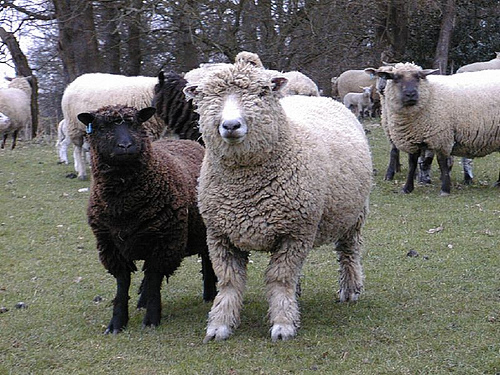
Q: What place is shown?
A: It is a field.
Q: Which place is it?
A: It is a field.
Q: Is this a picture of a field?
A: Yes, it is showing a field.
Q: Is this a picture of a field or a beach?
A: It is showing a field.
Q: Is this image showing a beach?
A: No, the picture is showing a field.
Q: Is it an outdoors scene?
A: Yes, it is outdoors.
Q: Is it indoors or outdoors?
A: It is outdoors.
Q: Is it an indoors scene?
A: No, it is outdoors.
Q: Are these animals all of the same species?
A: Yes, all the animals are sheep.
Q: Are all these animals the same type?
A: Yes, all the animals are sheep.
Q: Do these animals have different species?
A: No, all the animals are sheep.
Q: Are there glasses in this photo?
A: No, there are no glasses.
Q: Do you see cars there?
A: No, there are no cars.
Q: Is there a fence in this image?
A: Yes, there is a fence.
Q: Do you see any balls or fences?
A: Yes, there is a fence.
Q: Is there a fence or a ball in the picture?
A: Yes, there is a fence.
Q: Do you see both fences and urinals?
A: No, there is a fence but no urinals.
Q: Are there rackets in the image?
A: No, there are no rackets.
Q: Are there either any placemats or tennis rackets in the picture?
A: No, there are no tennis rackets or placemats.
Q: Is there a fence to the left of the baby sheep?
A: Yes, there is a fence to the left of the sheep.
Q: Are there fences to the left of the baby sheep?
A: Yes, there is a fence to the left of the sheep.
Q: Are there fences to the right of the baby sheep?
A: No, the fence is to the left of the sheep.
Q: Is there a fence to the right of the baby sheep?
A: No, the fence is to the left of the sheep.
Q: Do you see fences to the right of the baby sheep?
A: No, the fence is to the left of the sheep.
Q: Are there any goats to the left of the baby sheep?
A: No, there is a fence to the left of the sheep.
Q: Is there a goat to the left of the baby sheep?
A: No, there is a fence to the left of the sheep.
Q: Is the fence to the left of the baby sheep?
A: Yes, the fence is to the left of the sheep.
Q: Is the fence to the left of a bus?
A: No, the fence is to the left of the sheep.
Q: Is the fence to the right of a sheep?
A: Yes, the fence is to the right of a sheep.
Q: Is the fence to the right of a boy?
A: No, the fence is to the right of a sheep.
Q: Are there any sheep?
A: Yes, there is a sheep.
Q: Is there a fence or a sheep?
A: Yes, there is a sheep.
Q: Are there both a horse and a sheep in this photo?
A: No, there is a sheep but no horses.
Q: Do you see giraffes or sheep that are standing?
A: Yes, the sheep is standing.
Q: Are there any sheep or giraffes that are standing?
A: Yes, the sheep is standing.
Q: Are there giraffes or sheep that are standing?
A: Yes, the sheep is standing.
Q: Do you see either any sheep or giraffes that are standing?
A: Yes, the sheep is standing.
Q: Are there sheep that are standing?
A: Yes, there is a sheep that is standing.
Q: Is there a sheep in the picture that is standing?
A: Yes, there is a sheep that is standing.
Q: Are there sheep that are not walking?
A: Yes, there is a sheep that is standing.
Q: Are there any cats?
A: No, there are no cats.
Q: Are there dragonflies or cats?
A: No, there are no cats or dragonflies.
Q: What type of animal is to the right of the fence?
A: The animal is a sheep.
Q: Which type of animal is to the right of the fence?
A: The animal is a sheep.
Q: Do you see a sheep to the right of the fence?
A: Yes, there is a sheep to the right of the fence.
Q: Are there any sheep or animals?
A: Yes, there is a sheep.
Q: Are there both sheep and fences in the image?
A: Yes, there are both a sheep and a fence.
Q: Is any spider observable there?
A: No, there are no spiders.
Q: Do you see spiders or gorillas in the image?
A: No, there are no spiders or gorillas.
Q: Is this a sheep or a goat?
A: This is a sheep.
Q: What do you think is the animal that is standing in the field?
A: The animal is a sheep.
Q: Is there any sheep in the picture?
A: Yes, there is a sheep.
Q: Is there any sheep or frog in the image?
A: Yes, there is a sheep.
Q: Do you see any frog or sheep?
A: Yes, there is a sheep.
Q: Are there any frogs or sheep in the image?
A: Yes, there is a sheep.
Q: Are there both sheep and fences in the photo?
A: Yes, there are both a sheep and a fence.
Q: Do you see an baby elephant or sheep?
A: Yes, there is a baby sheep.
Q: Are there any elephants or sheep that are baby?
A: Yes, the sheep is a baby.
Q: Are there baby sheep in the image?
A: Yes, there is a baby sheep.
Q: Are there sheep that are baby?
A: Yes, there is a sheep that is a baby.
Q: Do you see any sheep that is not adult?
A: Yes, there is an baby sheep.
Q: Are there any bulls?
A: No, there are no bulls.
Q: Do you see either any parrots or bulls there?
A: No, there are no bulls or parrots.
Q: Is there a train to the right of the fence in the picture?
A: No, there is a sheep to the right of the fence.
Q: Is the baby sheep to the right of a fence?
A: Yes, the sheep is to the right of a fence.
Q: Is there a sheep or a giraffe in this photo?
A: Yes, there is a sheep.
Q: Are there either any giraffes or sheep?
A: Yes, there is a sheep.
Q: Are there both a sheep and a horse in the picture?
A: No, there is a sheep but no horses.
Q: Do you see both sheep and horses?
A: No, there is a sheep but no horses.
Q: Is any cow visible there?
A: No, there are no cows.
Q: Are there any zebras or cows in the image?
A: No, there are no cows or zebras.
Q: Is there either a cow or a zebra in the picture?
A: No, there are no cows or zebras.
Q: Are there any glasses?
A: No, there are no glasses.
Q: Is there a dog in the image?
A: No, there are no dogs.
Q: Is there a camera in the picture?
A: Yes, there is a camera.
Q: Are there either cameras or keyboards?
A: Yes, there is a camera.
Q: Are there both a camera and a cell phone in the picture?
A: No, there is a camera but no cell phones.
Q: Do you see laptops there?
A: No, there are no laptops.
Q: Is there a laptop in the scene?
A: No, there are no laptops.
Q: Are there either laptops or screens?
A: No, there are no laptops or screens.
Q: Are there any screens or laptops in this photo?
A: No, there are no laptops or screens.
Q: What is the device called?
A: The device is a camera.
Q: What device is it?
A: The device is a camera.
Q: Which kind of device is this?
A: This is a camera.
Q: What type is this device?
A: This is a camera.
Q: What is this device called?
A: This is a camera.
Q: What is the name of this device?
A: This is a camera.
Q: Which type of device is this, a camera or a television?
A: This is a camera.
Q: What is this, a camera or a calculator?
A: This is a camera.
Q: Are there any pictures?
A: No, there are no pictures.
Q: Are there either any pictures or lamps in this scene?
A: No, there are no pictures or lamps.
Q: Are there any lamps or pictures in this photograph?
A: No, there are no pictures or lamps.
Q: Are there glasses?
A: No, there are no glasses.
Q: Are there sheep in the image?
A: Yes, there is a sheep.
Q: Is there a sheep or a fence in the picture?
A: Yes, there is a sheep.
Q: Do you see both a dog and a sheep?
A: No, there is a sheep but no dogs.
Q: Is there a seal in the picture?
A: No, there are no seals.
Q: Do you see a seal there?
A: No, there are no seals.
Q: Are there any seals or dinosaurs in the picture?
A: No, there are no seals or dinosaurs.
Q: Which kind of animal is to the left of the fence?
A: The animal is a sheep.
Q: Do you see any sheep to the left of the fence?
A: Yes, there is a sheep to the left of the fence.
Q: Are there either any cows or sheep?
A: Yes, there is a sheep.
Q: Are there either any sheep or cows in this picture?
A: Yes, there is a sheep.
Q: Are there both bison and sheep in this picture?
A: No, there is a sheep but no bison.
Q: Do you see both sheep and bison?
A: No, there is a sheep but no bison.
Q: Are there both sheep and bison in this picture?
A: No, there is a sheep but no bison.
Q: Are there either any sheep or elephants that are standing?
A: Yes, the sheep is standing.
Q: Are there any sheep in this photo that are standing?
A: Yes, there is a sheep that is standing.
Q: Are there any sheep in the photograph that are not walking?
A: Yes, there is a sheep that is standing.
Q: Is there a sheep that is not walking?
A: Yes, there is a sheep that is standing.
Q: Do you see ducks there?
A: No, there are no ducks.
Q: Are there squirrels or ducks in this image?
A: No, there are no ducks or squirrels.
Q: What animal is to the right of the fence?
A: The animal is a sheep.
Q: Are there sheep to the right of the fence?
A: Yes, there is a sheep to the right of the fence.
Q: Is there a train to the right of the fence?
A: No, there is a sheep to the right of the fence.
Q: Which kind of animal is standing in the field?
A: The animal is a sheep.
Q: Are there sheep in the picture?
A: Yes, there is a sheep.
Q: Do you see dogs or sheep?
A: Yes, there is a sheep.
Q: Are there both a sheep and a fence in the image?
A: Yes, there are both a sheep and a fence.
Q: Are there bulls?
A: No, there are no bulls.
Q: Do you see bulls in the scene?
A: No, there are no bulls.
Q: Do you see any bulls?
A: No, there are no bulls.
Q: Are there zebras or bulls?
A: No, there are no bulls or zebras.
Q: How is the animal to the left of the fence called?
A: The animal is a sheep.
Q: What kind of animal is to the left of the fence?
A: The animal is a sheep.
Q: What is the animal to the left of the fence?
A: The animal is a sheep.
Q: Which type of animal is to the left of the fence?
A: The animal is a sheep.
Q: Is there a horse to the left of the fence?
A: No, there is a sheep to the left of the fence.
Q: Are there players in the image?
A: No, there are no players.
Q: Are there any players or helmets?
A: No, there are no players or helmets.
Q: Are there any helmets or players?
A: No, there are no players or helmets.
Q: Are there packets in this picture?
A: No, there are no packets.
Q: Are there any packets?
A: No, there are no packets.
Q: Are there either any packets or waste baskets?
A: No, there are no packets or waste baskets.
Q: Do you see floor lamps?
A: No, there are no floor lamps.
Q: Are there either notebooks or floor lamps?
A: No, there are no floor lamps or notebooks.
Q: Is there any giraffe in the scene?
A: No, there are no giraffes.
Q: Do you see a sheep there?
A: Yes, there is a sheep.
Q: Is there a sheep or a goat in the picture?
A: Yes, there is a sheep.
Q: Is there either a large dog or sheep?
A: Yes, there is a large sheep.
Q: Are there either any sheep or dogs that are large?
A: Yes, the sheep is large.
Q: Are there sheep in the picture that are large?
A: Yes, there is a large sheep.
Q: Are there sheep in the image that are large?
A: Yes, there is a sheep that is large.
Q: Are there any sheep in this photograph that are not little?
A: Yes, there is a large sheep.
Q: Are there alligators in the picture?
A: No, there are no alligators.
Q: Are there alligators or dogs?
A: No, there are no alligators or dogs.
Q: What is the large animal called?
A: The animal is a sheep.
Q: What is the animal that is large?
A: The animal is a sheep.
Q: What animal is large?
A: The animal is a sheep.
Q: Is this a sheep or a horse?
A: This is a sheep.